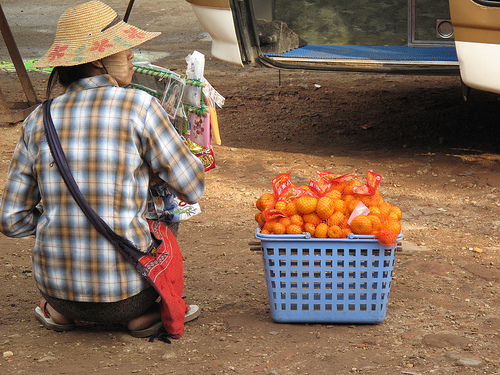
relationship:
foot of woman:
[37, 297, 68, 329] [7, 3, 204, 332]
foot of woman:
[128, 304, 198, 330] [7, 3, 204, 332]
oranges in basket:
[256, 175, 402, 240] [256, 223, 402, 326]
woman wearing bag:
[7, 3, 204, 332] [141, 219, 186, 336]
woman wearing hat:
[7, 3, 204, 332] [36, 1, 161, 66]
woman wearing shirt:
[7, 3, 204, 332] [5, 76, 202, 302]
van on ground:
[191, 1, 499, 91] [2, 40, 499, 374]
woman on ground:
[7, 3, 204, 332] [2, 40, 499, 374]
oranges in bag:
[256, 175, 402, 240] [265, 173, 317, 234]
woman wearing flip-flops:
[7, 3, 204, 332] [35, 305, 198, 334]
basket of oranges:
[256, 223, 402, 326] [256, 175, 402, 240]